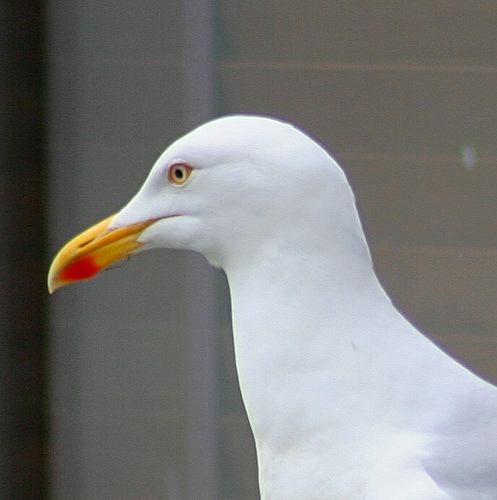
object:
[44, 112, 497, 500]
seagull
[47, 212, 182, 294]
beak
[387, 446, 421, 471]
feather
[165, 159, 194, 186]
eye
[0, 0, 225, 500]
structure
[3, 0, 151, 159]
background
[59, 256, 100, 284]
spot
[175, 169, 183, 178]
pupil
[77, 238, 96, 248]
hole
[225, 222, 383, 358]
neck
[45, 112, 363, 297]
head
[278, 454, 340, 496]
feather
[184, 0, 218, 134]
fram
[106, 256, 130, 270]
string